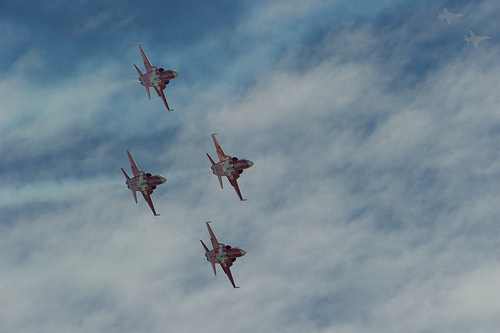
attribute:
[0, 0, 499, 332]
sky — blue , white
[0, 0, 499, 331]
clouds — white, several fluffy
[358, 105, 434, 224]
cloud — white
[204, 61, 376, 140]
cloud — white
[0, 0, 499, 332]
cloud — white 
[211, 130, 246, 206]
wings — tail , jets 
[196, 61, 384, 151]
cloud — white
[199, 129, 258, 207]
jet — portion , red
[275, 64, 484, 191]
cloud — white